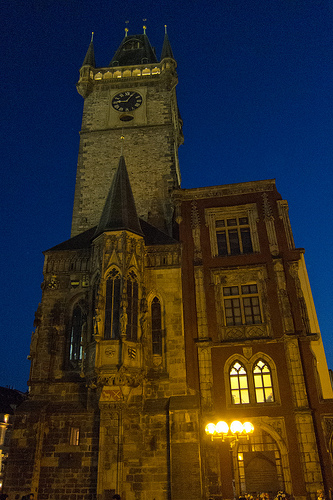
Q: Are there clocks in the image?
A: Yes, there is a clock.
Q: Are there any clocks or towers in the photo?
A: Yes, there is a clock.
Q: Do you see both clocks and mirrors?
A: No, there is a clock but no mirrors.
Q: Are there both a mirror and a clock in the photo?
A: No, there is a clock but no mirrors.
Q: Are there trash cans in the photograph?
A: No, there are no trash cans.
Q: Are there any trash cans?
A: No, there are no trash cans.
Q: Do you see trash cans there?
A: No, there are no trash cans.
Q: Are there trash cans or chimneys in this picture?
A: No, there are no trash cans or chimneys.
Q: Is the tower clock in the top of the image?
A: Yes, the clock is in the top of the image.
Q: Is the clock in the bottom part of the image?
A: No, the clock is in the top of the image.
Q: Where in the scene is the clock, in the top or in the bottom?
A: The clock is in the top of the image.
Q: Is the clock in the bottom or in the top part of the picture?
A: The clock is in the top of the image.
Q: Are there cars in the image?
A: No, there are no cars.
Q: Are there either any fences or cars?
A: No, there are no cars or fences.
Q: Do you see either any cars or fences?
A: No, there are no cars or fences.